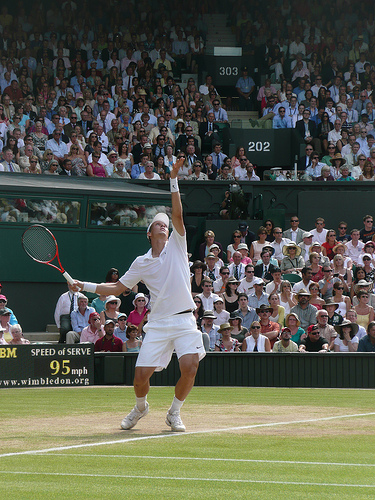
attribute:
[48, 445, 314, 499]
surface — green, white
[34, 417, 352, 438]
line — white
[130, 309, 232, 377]
shorts — white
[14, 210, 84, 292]
racquet — red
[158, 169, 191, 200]
band — white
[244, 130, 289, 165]
numbers — white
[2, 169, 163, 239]
background — green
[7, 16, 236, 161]
spectators — watching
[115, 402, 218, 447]
shoes — white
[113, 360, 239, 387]
knees — bent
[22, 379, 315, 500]
turf — worn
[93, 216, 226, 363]
uniform — white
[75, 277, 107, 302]
bands — white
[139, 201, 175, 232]
hat — white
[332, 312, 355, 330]
hat — floppy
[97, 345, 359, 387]
wall — low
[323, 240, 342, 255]
top — red